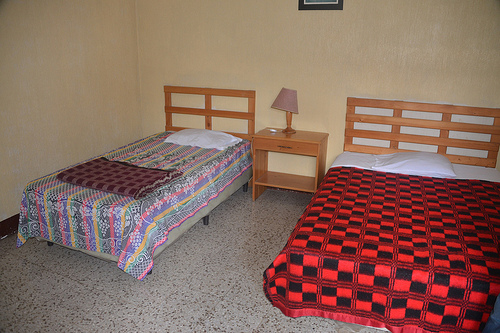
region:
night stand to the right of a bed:
[248, 125, 328, 198]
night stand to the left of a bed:
[250, 127, 322, 189]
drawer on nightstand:
[253, 136, 318, 156]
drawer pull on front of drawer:
[276, 143, 290, 150]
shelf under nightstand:
[256, 168, 313, 196]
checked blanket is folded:
[55, 153, 182, 203]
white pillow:
[164, 124, 241, 156]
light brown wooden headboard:
[162, 83, 254, 135]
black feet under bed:
[202, 214, 209, 224]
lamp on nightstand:
[271, 86, 302, 131]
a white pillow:
[372, 142, 456, 173]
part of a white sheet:
[327, 147, 373, 171]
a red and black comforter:
[263, 160, 493, 331]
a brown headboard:
[160, 84, 255, 136]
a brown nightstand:
[251, 124, 326, 199]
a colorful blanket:
[16, 130, 255, 277]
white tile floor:
[1, 186, 392, 331]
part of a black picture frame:
[294, 0, 346, 10]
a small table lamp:
[270, 84, 305, 134]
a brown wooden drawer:
[253, 138, 315, 158]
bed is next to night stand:
[13, 85, 255, 278]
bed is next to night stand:
[261, 96, 494, 329]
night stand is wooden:
[252, 126, 328, 205]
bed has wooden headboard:
[164, 83, 253, 146]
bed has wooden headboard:
[343, 96, 497, 171]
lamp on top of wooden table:
[272, 86, 301, 134]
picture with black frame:
[295, 0, 341, 9]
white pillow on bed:
[163, 125, 244, 153]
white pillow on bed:
[373, 151, 454, 175]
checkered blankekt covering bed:
[261, 166, 494, 329]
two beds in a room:
[38, 80, 490, 311]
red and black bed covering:
[277, 173, 490, 332]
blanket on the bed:
[36, 148, 168, 197]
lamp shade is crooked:
[270, 81, 302, 123]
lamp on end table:
[253, 90, 323, 197]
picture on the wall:
[279, 0, 373, 11]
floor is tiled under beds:
[12, 270, 266, 332]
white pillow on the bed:
[165, 128, 245, 145]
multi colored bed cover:
[28, 190, 185, 269]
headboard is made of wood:
[327, 103, 482, 159]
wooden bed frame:
[334, 86, 499, 180]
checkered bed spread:
[256, 163, 494, 331]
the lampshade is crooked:
[266, 76, 303, 121]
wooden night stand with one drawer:
[245, 108, 328, 206]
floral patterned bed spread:
[14, 129, 255, 279]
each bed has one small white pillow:
[152, 119, 486, 181]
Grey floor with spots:
[25, 277, 115, 332]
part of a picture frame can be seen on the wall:
[295, 0, 347, 15]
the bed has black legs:
[200, 183, 252, 235]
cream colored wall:
[20, 27, 146, 104]